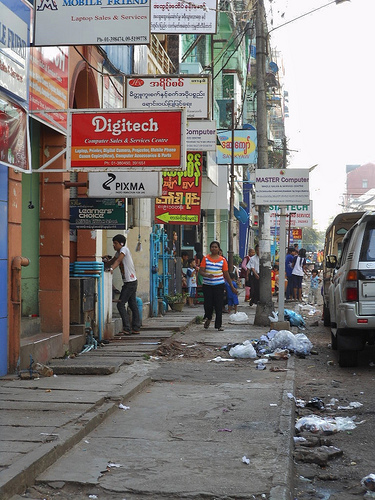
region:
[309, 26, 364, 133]
Sky is white color.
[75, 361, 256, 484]
Sidwalk is grey color.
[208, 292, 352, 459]
Sidewalk is dirty with platic bags.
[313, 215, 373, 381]
Cars are parked in sides of the road.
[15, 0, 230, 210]
Boards are attached to the building wall.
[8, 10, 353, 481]
Day time picture.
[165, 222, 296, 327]
People are walking in the sidewalk.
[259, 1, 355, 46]
Street light is attached to the pole.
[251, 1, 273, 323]
Pole is grey color.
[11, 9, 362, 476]
Picture is taken outdoor.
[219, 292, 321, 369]
Garbage on the street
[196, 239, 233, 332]
Woman with a striped tank top over an orange shirt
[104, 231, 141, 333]
Man leaning against building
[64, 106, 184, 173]
Digitech sign hanging from the building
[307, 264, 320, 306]
Child standing at the curb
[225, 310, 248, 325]
Plastic bag on the pavement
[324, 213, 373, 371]
Car parked at the curb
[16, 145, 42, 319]
Green door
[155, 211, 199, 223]
Yellow sign pointing left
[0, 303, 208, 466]
Uneven pavement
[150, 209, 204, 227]
Arrow on the sign.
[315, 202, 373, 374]
Car parked on the side of the road.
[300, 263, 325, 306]
Kid in the road.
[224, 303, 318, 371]
Trash on the ground.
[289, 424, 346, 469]
Large rocks on the road.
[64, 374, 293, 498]
Dip in the sidewalk.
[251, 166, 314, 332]
Sign on a pole.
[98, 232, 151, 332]
The person is leaning on a partial wall.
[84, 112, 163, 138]
Digitech on the sign.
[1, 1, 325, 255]
Signs on the building.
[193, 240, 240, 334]
Lady wearing multi-color striped shirt.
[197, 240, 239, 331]
Lady wearing black pants.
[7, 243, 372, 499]
Trash strewn all over ground.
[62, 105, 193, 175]
Red and orange sign with white writing.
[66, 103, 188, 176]
Red and orange sign with white border.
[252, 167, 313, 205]
White advertising sign with purple letters.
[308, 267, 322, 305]
Little girl wearing blue shirt with designs.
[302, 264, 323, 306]
Little girl wearing off white pants.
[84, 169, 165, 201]
White advertising sign with black letters.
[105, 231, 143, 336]
Boy wearing white t-shirt and black pants.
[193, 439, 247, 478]
part of a floor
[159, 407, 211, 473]
part of a floor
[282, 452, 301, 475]
edge of a road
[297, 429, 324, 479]
part of a waste